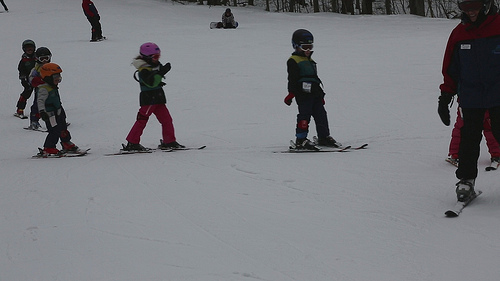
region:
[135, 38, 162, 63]
a pink helmet on a little girl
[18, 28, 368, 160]
Young children learning to ski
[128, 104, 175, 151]
red snow pants with a thite stripe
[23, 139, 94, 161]
little skis for little people are shorter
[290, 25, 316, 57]
a little boy wears a black helmet with white framed snow goggles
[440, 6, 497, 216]
an adult skier is nearby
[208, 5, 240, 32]
a child sits in the snow with his snow board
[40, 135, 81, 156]
a pair of red ski boots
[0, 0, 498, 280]
ski tracks in the snow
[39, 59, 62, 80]
one child wears an orange helmet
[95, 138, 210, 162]
Child on skis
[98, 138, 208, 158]
Child is on skis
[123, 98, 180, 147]
Child is wearing pants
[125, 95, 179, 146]
Child is wearing red pants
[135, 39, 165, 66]
Child wearing a pink helmet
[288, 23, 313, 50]
Child wearing a black helmet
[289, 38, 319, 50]
Child is wearing white goggles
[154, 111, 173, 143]
red pants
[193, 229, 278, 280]
the snow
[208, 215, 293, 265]
the snow is white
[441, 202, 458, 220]
a ski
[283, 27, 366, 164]
the child is skiing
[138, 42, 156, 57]
a purple helmet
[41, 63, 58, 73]
an orange helmet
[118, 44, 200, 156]
the child is skiing in the snow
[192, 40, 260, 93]
the white snow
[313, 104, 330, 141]
the child is wearing pants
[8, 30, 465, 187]
kids learning to ski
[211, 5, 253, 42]
a person sitting on the snow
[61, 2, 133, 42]
a person snowboarding down a slope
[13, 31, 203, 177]
kids following other kids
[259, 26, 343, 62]
a kid wearing a blue helmet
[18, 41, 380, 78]
kids wearing snow goggles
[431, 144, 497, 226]
an adult wearing skis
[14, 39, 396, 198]
kids sking on a slope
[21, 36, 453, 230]
kids sking on snow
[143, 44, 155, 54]
the helmet is light pink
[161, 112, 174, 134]
the pants are dark pink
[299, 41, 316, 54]
the goggles are silver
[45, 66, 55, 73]
the helmet is orange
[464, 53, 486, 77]
the coat is dark blue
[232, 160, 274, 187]
the snow has tracks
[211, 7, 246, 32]
the person is on the ground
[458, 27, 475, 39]
the coat is red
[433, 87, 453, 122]
the gloves are black